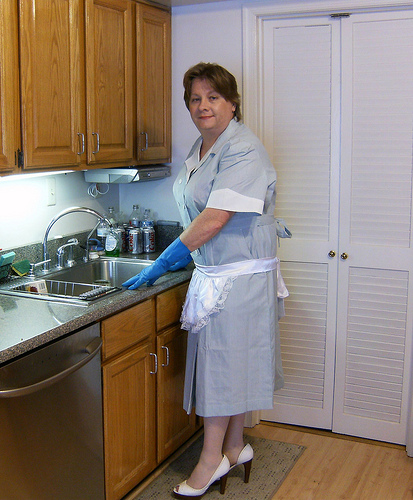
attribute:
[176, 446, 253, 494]
heels — white, high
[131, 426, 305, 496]
mat — small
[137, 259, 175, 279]
glove — blue, rubber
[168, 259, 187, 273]
glove — rubber, blue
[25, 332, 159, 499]
dishwasher — grey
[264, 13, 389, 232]
door — white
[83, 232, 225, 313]
gloves — blue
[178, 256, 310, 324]
apron — white, laced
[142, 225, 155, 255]
can — empty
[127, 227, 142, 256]
can — empty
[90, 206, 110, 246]
bottle — empty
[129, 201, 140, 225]
bottle — empty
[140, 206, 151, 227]
bottle — empty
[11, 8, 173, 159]
cabinets — brown, wooden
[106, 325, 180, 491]
cabinets — wooden, brown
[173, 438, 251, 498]
heels stiletto — white, brown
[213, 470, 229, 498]
heel — tall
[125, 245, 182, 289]
gloves — blue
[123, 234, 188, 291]
glove — blue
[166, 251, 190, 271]
glove — blue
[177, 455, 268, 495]
heels — brown, white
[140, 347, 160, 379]
handle — silver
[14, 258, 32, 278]
sponge — cleaning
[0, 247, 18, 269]
sponge — cleaning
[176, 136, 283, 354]
maid uniform — blue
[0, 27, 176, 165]
cupboards — wooden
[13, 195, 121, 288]
faucets — chrome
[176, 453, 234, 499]
high heel — brown, white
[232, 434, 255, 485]
high heel — brown, white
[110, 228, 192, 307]
gloves — blue, rubber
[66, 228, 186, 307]
sink — silver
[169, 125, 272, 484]
maid outfit — blue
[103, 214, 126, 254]
detergent — green, dish detergent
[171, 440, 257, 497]
shoes — white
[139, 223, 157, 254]
can — silver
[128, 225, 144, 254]
can — silver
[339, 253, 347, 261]
knob — small, gold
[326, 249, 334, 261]
knob — small, gold